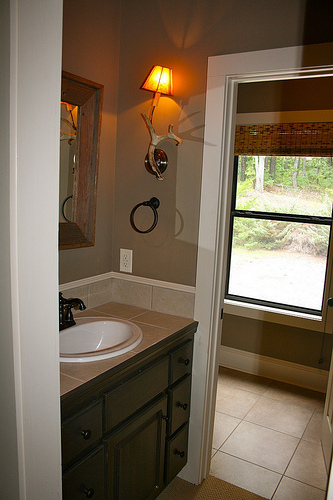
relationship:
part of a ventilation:
[295, 0, 332, 69] [297, 3, 333, 76]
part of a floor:
[209, 373, 256, 476] [156, 373, 333, 498]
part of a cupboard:
[62, 373, 130, 499] [61, 322, 197, 499]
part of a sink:
[61, 319, 130, 359] [57, 314, 143, 366]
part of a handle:
[133, 217, 157, 233] [128, 198, 165, 235]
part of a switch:
[120, 260, 132, 274] [120, 248, 136, 273]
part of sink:
[61, 319, 130, 359] [57, 314, 143, 366]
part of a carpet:
[156, 479, 207, 500] [149, 471, 265, 499]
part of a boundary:
[229, 233, 283, 252] [234, 232, 327, 258]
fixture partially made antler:
[135, 92, 182, 176] [142, 106, 180, 178]